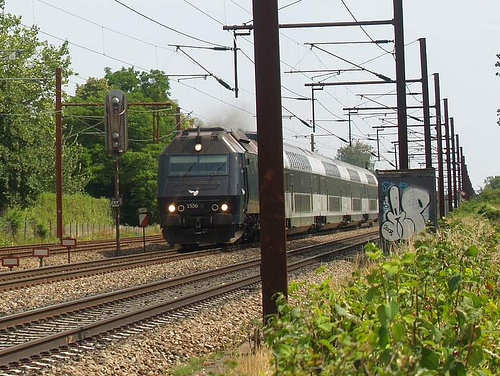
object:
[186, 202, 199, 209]
1536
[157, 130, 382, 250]
train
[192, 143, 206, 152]
headlights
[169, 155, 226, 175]
windows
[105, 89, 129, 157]
train signal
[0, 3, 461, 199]
power cables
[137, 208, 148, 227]
sign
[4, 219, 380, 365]
train tracks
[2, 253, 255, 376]
gravel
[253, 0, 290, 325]
pole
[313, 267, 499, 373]
green plants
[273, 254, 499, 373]
plants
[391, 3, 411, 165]
electrical post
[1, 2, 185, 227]
forest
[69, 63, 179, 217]
tree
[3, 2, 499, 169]
sky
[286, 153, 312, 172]
windows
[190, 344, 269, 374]
grass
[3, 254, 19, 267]
signs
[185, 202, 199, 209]
number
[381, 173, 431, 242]
graffiti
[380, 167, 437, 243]
sign